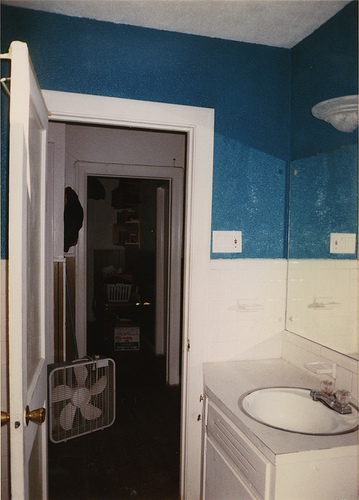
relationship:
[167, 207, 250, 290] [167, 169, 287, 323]
switch on wall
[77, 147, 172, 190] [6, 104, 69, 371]
casing on door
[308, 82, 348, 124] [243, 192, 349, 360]
reflection in mirror